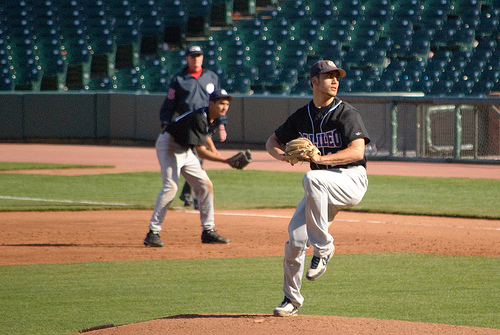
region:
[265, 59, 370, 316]
pitcher is pitching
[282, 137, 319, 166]
pitcher wearing leather catcher's mitt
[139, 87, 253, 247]
catcher behind pitcher is leaning forward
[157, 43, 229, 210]
base coach standing behind catcher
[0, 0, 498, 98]
empty green bleachers behind players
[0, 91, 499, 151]
green wall in front of bleachers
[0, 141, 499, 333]
players standing on baseball field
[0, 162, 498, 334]
field has short patches of grass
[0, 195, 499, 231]
white line on field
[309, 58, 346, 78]
pitcher wearing baseball cap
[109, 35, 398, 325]
two players out in the field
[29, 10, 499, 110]
empty seats in the stadium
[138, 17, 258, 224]
coach standing and watching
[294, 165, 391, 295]
one leg up in the air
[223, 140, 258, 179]
black baseball glove on hand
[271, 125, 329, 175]
brown baseball glove on hand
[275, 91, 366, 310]
black shirt and gray pants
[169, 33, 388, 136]
all three men wear hats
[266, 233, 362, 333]
black and white shoes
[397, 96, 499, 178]
fence at side of field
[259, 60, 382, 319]
a baseball player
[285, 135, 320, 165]
a base ball glove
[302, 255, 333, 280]
a black and white shoe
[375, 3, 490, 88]
green chairs in th edistance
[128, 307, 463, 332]
a pitchers mound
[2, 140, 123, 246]
grass and dirt on a ball field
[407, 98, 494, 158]
a screened in dug out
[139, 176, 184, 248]
a mans right leg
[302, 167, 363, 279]
a mans left leg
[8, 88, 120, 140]
a gray wall in the distance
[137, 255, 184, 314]
part of a ground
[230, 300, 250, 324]
part of a shade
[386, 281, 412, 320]
part of a ground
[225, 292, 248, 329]
part of a shade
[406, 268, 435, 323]
part of a ground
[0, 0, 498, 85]
empty stadium with green seats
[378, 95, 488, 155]
green railings to dugout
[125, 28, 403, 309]
practice for baseball team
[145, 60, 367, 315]
base player and pitcher wear mitts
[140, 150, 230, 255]
knees of white pants covered in red dirt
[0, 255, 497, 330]
neatly edged green turf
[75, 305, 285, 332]
shadow of the pitcher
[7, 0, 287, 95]
stairs accessing higher stadium seating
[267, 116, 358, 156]
Galileo team name on jersey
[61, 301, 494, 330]
slightly raised pitchers mound